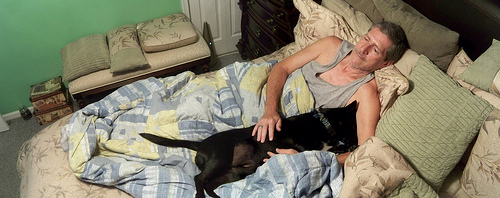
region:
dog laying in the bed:
[112, 118, 377, 188]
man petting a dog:
[238, 81, 308, 146]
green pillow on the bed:
[371, 71, 496, 146]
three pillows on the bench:
[48, 30, 223, 73]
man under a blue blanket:
[136, 69, 309, 191]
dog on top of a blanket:
[147, 99, 370, 169]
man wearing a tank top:
[293, 41, 366, 121]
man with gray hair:
[361, 17, 418, 73]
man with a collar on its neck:
[311, 104, 333, 140]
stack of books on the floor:
[22, 78, 74, 120]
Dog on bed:
[136, 102, 362, 194]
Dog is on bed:
[134, 98, 363, 196]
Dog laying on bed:
[135, 99, 361, 196]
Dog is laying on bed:
[140, 100, 358, 196]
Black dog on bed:
[140, 97, 360, 197]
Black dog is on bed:
[137, 97, 360, 195]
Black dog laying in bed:
[129, 102, 363, 195]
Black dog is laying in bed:
[139, 97, 363, 196]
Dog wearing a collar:
[313, 102, 346, 146]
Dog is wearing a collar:
[312, 102, 346, 150]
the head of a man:
[343, 19, 438, 96]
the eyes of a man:
[356, 20, 404, 67]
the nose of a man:
[359, 30, 379, 61]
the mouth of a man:
[336, 48, 370, 77]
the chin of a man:
[323, 50, 362, 90]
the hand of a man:
[250, 102, 305, 137]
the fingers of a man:
[225, 100, 305, 157]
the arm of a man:
[241, 43, 324, 138]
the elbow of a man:
[251, 45, 311, 97]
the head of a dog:
[308, 86, 405, 158]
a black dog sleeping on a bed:
[141, 100, 360, 197]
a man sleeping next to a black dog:
[139, 18, 407, 197]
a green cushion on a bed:
[374, 56, 489, 193]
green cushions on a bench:
[62, 11, 201, 84]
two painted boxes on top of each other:
[28, 73, 74, 128]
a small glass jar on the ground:
[18, 105, 33, 120]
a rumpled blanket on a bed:
[64, 59, 345, 195]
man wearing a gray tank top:
[303, 40, 375, 108]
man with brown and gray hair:
[351, 19, 408, 73]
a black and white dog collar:
[313, 106, 343, 149]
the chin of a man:
[334, 48, 366, 75]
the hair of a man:
[358, 10, 443, 52]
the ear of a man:
[362, 53, 419, 85]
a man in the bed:
[193, 8, 463, 166]